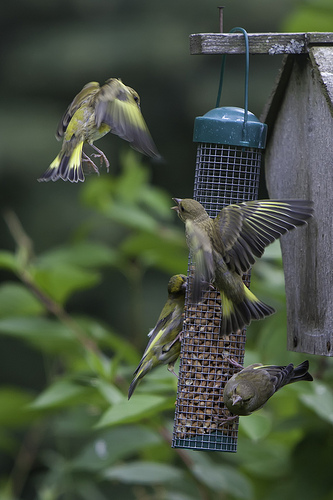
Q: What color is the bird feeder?
A: The feeder is green.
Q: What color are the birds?
A: The birds are brown and yellow.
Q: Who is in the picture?
A: Birds are in the picture.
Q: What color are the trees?
A: The trees are green.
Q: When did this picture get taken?
A: It was taken in the day time.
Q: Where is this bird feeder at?
A: It is hanging on a bird house.